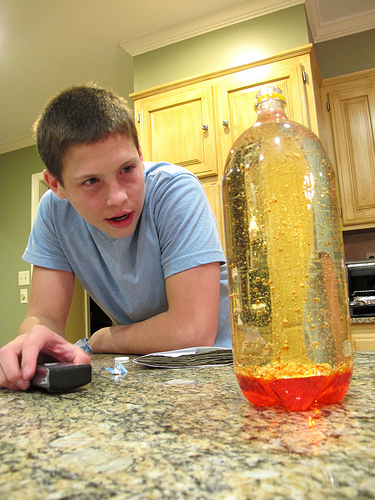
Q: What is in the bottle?
A: A red liquid.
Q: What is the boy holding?
A: A mobile phone.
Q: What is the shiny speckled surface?
A: The countertop.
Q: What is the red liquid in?
A: A clear plastic bottle.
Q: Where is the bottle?
A: On top of the counter.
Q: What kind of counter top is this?
A: Marble.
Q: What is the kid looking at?
A: A bottle with liquid in it.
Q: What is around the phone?
A: The hand of a kid.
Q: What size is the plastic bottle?
A: A two liter.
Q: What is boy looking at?
A: The bottle.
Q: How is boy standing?
A: Leaning on counter.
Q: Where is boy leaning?
A: On counter.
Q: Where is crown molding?
A: Between wall and ceiling.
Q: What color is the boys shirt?
A: Blue.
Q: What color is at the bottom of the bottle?
A: Red.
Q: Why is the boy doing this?
A: Project.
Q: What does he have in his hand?
A: Remote.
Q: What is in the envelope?
A: Money.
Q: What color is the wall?
A: Green.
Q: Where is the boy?
A: On the kitchen table.